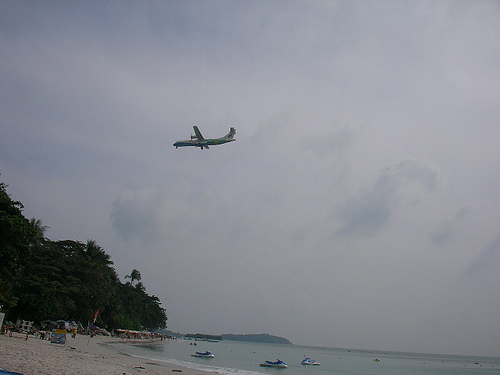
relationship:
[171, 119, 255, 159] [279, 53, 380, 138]
plane in sky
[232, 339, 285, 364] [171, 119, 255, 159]
water below plane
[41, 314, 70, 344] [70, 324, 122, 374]
people on beach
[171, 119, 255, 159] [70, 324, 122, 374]
plane above beach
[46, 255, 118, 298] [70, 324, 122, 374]
trees on beach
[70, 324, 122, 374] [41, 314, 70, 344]
beach with people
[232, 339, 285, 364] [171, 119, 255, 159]
water near plane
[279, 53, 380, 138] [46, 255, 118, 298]
sky near trees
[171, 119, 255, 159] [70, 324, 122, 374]
plane on beach